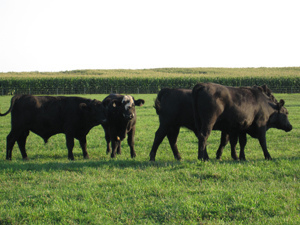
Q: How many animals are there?
A: Four.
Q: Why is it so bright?
A: Sunny.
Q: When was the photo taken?
A: Day time.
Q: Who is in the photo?
A: Cows.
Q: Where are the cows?
A: The grass.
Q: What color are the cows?
A: Brown.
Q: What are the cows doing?
A: Standing.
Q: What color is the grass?
A: Green.